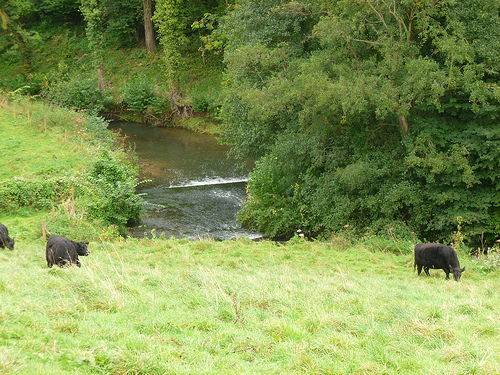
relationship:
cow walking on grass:
[37, 216, 105, 275] [29, 273, 420, 373]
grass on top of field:
[138, 268, 282, 321] [1, 232, 487, 373]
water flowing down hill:
[128, 112, 260, 247] [13, 49, 187, 126]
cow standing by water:
[405, 235, 467, 285] [139, 141, 244, 226]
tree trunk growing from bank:
[133, 28, 162, 61] [1, 88, 496, 373]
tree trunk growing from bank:
[87, 63, 120, 101] [6, 28, 488, 160]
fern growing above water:
[98, 173, 143, 223] [135, 128, 198, 192]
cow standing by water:
[413, 243, 465, 282] [146, 166, 247, 236]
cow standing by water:
[413, 243, 465, 282] [103, 118, 270, 240]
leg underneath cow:
[415, 266, 422, 276] [413, 243, 465, 282]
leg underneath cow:
[422, 266, 429, 278] [413, 243, 465, 282]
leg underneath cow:
[443, 269, 450, 280] [413, 243, 465, 282]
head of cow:
[449, 265, 464, 280] [413, 243, 465, 282]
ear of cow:
[457, 267, 467, 276] [408, 239, 465, 284]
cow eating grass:
[413, 243, 465, 282] [3, 245, 493, 373]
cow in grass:
[413, 243, 465, 282] [0, 217, 498, 372]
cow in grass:
[46, 235, 81, 268] [0, 217, 498, 372]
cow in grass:
[0, 218, 16, 252] [0, 217, 498, 372]